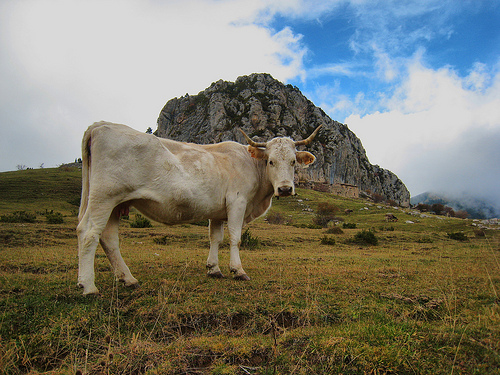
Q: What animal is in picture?
A: Cow.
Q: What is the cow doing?
A: Looking at camera.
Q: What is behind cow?
A: A rock.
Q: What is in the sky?
A: Clouds.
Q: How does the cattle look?
A: Healthy.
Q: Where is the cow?
A: In a field.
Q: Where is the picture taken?
A: A pasture.